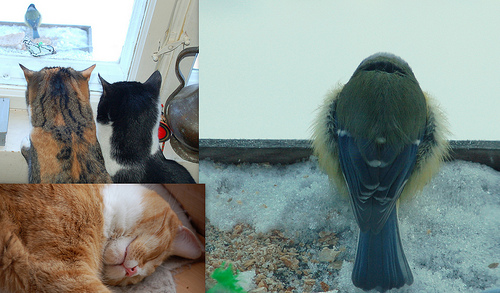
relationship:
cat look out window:
[95, 69, 197, 182] [6, 9, 196, 143]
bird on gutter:
[308, 44, 448, 291] [199, 134, 499, 197]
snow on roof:
[230, 173, 308, 220] [202, 153, 498, 287]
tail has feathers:
[342, 194, 420, 290] [355, 204, 404, 289]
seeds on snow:
[241, 236, 293, 281] [219, 184, 339, 291]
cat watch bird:
[95, 69, 197, 182] [21, 2, 42, 38]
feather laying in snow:
[211, 261, 239, 291] [218, 183, 311, 269]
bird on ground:
[308, 44, 448, 291] [216, 137, 498, 221]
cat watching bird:
[19, 59, 111, 182] [21, 0, 43, 36]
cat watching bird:
[95, 72, 196, 182] [21, 0, 43, 36]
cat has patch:
[1, 184, 204, 291] [93, 184, 138, 243]